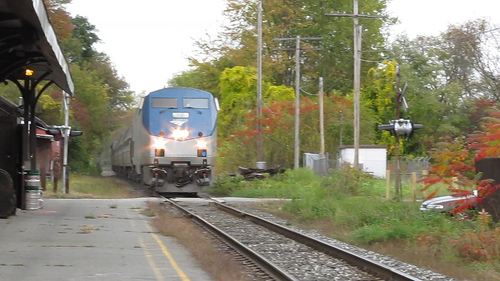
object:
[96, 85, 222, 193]
train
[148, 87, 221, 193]
front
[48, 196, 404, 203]
tracks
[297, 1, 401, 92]
trees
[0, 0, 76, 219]
station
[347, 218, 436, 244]
grass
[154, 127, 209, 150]
lights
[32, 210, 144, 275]
concrete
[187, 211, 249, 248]
straight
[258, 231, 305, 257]
forward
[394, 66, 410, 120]
sign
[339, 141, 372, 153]
right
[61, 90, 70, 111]
sign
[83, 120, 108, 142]
left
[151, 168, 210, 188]
engine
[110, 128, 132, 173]
passenger cars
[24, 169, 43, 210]
barrels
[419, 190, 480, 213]
car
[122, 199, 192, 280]
lines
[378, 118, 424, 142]
light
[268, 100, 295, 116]
leaves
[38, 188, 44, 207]
bottle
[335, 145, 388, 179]
shed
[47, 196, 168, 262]
street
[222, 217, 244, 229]
rocks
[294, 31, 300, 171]
electric lines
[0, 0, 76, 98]
overhang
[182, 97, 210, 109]
windows